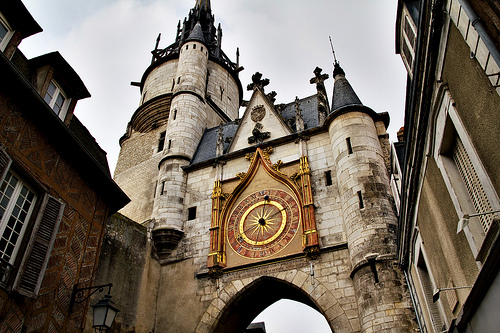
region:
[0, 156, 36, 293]
the window on the building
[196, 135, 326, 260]
the clock on the building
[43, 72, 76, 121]
the window on the building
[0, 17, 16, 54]
the window on the building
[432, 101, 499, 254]
the window on the building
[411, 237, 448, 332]
the window on the building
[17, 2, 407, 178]
a very clear sky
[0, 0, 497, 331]
this is a stoley building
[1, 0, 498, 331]
the building is made of stone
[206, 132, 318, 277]
the clock is gold and maroon in color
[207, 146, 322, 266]
large clock with roman numerals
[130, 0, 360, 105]
spires on a castle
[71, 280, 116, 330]
old oil lamp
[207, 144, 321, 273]
clock in red, gold, and brown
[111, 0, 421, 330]
castle constructed from large bricks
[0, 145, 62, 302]
tall window with open shutters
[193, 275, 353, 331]
tall arched entryway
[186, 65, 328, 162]
black roof on a castle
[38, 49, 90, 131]
attic window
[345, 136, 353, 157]
arrow slit on a castle spire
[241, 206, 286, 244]
Black hands on clock.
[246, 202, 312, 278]
Clock has brown face.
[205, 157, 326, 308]
Clock has gold edging.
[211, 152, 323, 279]
Decorative arch around clock.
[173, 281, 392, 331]
Large archway underneath clock.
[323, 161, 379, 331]
Bricks are grayish in color.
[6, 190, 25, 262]
White window on side of building.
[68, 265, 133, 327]
Light attached to side of building.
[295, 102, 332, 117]
Black roof on building.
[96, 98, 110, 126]
Sky is light and clear.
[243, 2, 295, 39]
part of some cloud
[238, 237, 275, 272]
edge of a clock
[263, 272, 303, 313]
edge of a hallway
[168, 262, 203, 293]
part of a wall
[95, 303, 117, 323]
part of a lamp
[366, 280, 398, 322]
part of a tower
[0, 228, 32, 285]
part of a window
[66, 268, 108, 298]
part of a handle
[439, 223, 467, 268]
part of a wall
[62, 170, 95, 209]
part of a wall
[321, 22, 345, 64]
a spike on the spire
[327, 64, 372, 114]
the top of a spire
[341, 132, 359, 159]
a window on the tower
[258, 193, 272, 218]
the hand of a clock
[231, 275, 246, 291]
a stone in the wall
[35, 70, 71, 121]
a window on the building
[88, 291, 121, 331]
a street lamp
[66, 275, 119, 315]
a street lamp pole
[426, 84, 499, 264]
a white window frame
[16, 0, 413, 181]
a gray sky